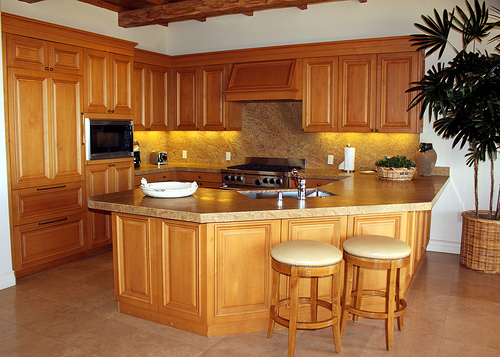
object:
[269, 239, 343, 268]
cushions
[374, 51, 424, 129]
cabinets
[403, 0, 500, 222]
plant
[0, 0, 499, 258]
wall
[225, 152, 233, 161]
socket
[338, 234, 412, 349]
bar stool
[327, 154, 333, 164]
socket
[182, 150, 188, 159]
socket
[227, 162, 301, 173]
range top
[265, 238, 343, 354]
bar stool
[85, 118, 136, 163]
microwave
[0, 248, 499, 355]
floor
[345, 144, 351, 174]
holder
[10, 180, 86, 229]
drawers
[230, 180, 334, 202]
sink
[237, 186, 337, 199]
sink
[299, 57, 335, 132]
cabinets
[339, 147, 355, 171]
paper towels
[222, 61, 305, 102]
hood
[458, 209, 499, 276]
pot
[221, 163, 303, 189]
oven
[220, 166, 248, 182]
knobs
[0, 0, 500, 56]
ceiling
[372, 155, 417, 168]
greenery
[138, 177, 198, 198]
bowl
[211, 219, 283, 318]
cabinettes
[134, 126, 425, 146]
lighting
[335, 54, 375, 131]
cabinets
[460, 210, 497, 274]
basket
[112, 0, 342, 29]
beams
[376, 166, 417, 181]
basket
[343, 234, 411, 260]
cushion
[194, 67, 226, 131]
cabinets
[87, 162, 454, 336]
counter